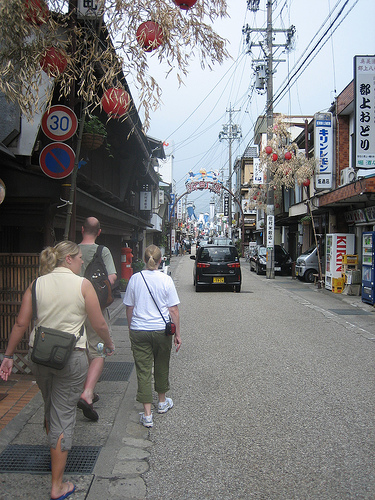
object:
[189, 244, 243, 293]
car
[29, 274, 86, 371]
bag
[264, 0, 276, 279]
pole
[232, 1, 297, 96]
power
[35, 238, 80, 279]
hair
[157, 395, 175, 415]
shoes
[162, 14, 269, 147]
cables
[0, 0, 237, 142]
tree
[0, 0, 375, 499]
picture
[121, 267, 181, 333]
t-shirt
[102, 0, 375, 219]
sky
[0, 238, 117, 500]
people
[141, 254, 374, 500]
down street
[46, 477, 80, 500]
flip flops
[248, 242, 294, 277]
cars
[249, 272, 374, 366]
sidewalk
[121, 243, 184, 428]
woman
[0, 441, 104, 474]
storm drain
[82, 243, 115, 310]
bag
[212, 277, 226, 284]
license plate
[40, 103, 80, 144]
sign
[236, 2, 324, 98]
power lines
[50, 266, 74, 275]
collared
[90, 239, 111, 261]
shoulder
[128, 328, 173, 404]
pants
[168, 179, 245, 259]
structure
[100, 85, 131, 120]
ball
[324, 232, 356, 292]
machine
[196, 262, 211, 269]
taillights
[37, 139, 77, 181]
sign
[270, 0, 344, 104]
wires